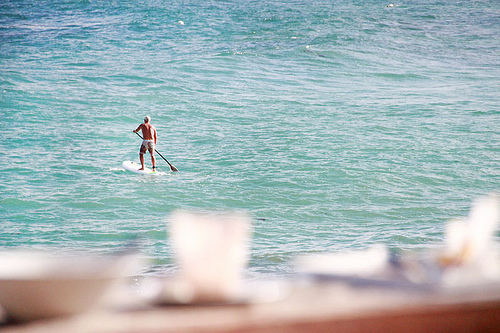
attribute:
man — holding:
[122, 111, 172, 154]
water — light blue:
[126, 55, 474, 247]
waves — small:
[36, 41, 247, 111]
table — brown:
[135, 264, 412, 330]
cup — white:
[148, 197, 281, 273]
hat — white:
[135, 96, 166, 125]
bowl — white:
[12, 240, 164, 310]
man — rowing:
[126, 98, 202, 174]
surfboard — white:
[96, 137, 156, 193]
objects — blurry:
[0, 190, 499, 320]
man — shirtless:
[134, 114, 156, 171]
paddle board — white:
[121, 157, 167, 177]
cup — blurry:
[167, 208, 253, 278]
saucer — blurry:
[127, 275, 287, 303]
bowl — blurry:
[1, 247, 147, 317]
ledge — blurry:
[2, 275, 499, 331]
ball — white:
[387, 2, 395, 8]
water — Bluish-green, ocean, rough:
[1, 1, 499, 286]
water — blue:
[183, 87, 414, 232]